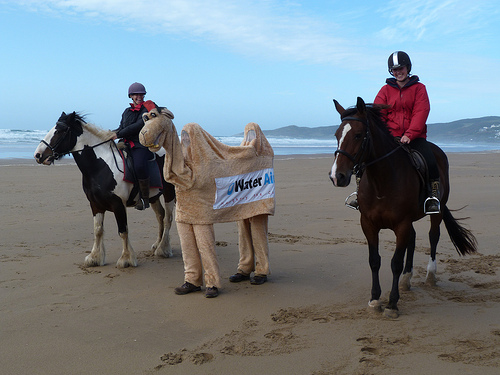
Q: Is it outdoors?
A: Yes, it is outdoors.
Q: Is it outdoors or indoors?
A: It is outdoors.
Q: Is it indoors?
A: No, it is outdoors.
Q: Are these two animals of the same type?
A: Yes, all the animals are horses.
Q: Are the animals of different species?
A: No, all the animals are horses.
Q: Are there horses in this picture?
A: Yes, there is a horse.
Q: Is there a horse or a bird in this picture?
A: Yes, there is a horse.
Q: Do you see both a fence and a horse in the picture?
A: No, there is a horse but no fences.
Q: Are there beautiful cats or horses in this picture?
A: Yes, there is a beautiful horse.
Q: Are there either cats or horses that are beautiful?
A: Yes, the horse is beautiful.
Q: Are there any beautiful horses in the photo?
A: Yes, there is a beautiful horse.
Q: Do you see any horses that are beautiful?
A: Yes, there is a horse that is beautiful.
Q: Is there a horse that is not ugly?
A: Yes, there is an beautiful horse.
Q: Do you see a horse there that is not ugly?
A: Yes, there is an beautiful horse.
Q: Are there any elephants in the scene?
A: No, there are no elephants.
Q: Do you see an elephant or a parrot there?
A: No, there are no elephants or parrots.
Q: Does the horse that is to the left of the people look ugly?
A: No, the horse is beautiful.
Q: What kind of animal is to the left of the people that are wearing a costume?
A: The animal is a horse.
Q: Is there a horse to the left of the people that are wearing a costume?
A: Yes, there is a horse to the left of the people.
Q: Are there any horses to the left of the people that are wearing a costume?
A: Yes, there is a horse to the left of the people.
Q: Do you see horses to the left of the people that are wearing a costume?
A: Yes, there is a horse to the left of the people.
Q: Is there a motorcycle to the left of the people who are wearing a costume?
A: No, there is a horse to the left of the people.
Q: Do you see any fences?
A: No, there are no fences.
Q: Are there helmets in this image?
A: Yes, there is a helmet.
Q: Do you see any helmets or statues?
A: Yes, there is a helmet.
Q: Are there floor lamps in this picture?
A: No, there are no floor lamps.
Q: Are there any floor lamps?
A: No, there are no floor lamps.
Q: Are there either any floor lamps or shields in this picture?
A: No, there are no floor lamps or shields.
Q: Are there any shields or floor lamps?
A: No, there are no floor lamps or shields.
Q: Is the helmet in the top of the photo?
A: Yes, the helmet is in the top of the image.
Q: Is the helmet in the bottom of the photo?
A: No, the helmet is in the top of the image.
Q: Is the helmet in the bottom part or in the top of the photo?
A: The helmet is in the top of the image.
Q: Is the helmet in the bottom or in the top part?
A: The helmet is in the top of the image.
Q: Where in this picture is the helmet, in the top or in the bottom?
A: The helmet is in the top of the image.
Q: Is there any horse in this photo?
A: Yes, there is a horse.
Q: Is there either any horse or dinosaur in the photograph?
A: Yes, there is a horse.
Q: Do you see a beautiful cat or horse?
A: Yes, there is a beautiful horse.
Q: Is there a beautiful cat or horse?
A: Yes, there is a beautiful horse.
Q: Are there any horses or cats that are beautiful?
A: Yes, the horse is beautiful.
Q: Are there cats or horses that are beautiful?
A: Yes, the horse is beautiful.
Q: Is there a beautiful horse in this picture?
A: Yes, there is a beautiful horse.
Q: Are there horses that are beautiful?
A: Yes, there is a horse that is beautiful.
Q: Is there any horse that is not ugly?
A: Yes, there is an beautiful horse.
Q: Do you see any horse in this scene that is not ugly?
A: Yes, there is an beautiful horse.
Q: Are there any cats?
A: No, there are no cats.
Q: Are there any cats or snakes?
A: No, there are no cats or snakes.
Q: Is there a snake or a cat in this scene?
A: No, there are no cats or snakes.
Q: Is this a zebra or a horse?
A: This is a horse.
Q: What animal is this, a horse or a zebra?
A: This is a horse.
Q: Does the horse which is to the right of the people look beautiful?
A: Yes, the horse is beautiful.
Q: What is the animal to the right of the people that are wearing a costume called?
A: The animal is a horse.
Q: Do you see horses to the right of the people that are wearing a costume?
A: Yes, there is a horse to the right of the people.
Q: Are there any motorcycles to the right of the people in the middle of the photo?
A: No, there is a horse to the right of the people.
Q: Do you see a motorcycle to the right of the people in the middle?
A: No, there is a horse to the right of the people.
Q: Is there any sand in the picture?
A: Yes, there is sand.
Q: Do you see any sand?
A: Yes, there is sand.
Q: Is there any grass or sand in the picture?
A: Yes, there is sand.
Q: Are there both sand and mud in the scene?
A: No, there is sand but no mud.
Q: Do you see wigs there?
A: No, there are no wigs.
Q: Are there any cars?
A: No, there are no cars.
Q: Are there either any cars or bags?
A: No, there are no cars or bags.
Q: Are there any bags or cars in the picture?
A: No, there are no cars or bags.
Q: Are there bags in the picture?
A: No, there are no bags.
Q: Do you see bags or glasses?
A: No, there are no bags or glasses.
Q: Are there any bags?
A: No, there are no bags.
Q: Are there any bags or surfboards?
A: No, there are no bags or surfboards.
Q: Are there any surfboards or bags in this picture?
A: No, there are no bags or surfboards.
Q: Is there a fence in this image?
A: No, there are no fences.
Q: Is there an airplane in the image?
A: No, there are no airplanes.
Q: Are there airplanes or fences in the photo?
A: No, there are no airplanes or fences.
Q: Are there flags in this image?
A: No, there are no flags.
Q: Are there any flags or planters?
A: No, there are no flags or planters.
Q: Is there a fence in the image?
A: No, there are no fences.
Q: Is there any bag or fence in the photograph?
A: No, there are no fences or bags.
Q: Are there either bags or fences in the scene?
A: No, there are no fences or bags.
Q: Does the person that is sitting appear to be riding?
A: Yes, the person is riding.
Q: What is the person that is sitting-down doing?
A: The person is riding.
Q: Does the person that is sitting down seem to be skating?
A: No, the person is riding.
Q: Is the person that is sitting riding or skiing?
A: The person is riding.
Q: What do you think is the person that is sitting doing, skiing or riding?
A: The person is riding.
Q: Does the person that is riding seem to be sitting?
A: Yes, the person is sitting.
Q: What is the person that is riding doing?
A: The person is sitting.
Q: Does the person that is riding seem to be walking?
A: No, the person is sitting.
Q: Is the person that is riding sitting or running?
A: The person is sitting.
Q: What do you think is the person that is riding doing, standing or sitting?
A: The person is sitting.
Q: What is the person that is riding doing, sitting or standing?
A: The person is sitting.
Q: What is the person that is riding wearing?
A: The person is wearing a helmet.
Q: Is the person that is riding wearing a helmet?
A: Yes, the person is wearing a helmet.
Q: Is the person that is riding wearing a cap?
A: No, the person is wearing a helmet.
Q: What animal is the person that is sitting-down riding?
A: The person is riding a horse.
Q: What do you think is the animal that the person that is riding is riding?
A: The animal is a horse.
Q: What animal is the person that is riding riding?
A: The person is riding a horse.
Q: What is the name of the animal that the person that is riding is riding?
A: The animal is a horse.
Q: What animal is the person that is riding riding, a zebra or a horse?
A: The person is riding a horse.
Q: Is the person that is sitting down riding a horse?
A: Yes, the person is riding a horse.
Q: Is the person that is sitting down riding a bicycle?
A: No, the person is riding a horse.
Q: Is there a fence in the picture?
A: No, there are no fences.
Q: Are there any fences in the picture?
A: No, there are no fences.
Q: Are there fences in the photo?
A: No, there are no fences.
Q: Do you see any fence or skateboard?
A: No, there are no fences or skateboards.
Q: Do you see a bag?
A: No, there are no bags.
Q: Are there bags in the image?
A: No, there are no bags.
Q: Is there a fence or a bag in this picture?
A: No, there are no bags or fences.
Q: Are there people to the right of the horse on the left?
A: Yes, there are people to the right of the horse.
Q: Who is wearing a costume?
A: The people are wearing a costume.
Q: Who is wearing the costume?
A: The people are wearing a costume.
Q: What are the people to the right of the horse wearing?
A: The people are wearing a costume.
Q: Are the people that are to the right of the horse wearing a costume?
A: Yes, the people are wearing a costume.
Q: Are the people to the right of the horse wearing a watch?
A: No, the people are wearing a costume.